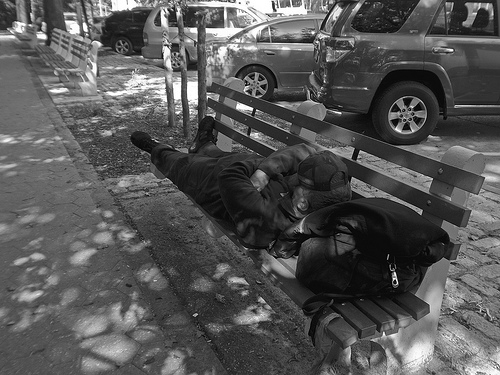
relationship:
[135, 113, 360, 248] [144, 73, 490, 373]
man on bench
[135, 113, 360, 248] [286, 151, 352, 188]
man has hat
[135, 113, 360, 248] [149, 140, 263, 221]
man wearing pants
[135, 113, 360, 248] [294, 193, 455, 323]
man using backpack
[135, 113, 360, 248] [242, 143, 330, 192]
man has arm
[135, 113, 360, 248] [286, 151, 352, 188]
man wearing hat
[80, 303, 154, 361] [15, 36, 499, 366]
sunlight on ground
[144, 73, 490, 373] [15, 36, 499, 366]
bench in ground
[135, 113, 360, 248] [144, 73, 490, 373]
man sleeping on bench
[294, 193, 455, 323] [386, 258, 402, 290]
backpack has buckle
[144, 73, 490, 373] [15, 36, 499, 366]
bench on ground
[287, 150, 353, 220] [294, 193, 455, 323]
head resting on backpack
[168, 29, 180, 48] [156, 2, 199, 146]
stake supporting trunk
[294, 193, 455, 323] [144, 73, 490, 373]
backpack on bench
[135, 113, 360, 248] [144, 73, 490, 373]
man laying on bench